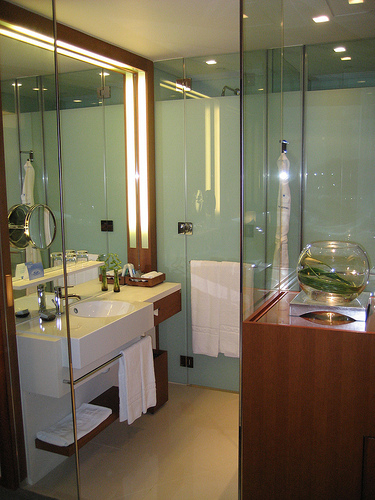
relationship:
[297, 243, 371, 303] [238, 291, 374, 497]
fishbowl on stand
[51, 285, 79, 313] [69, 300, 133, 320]
faucet over sink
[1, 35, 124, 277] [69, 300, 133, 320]
mirror over sink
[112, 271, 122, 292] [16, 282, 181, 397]
vase on counter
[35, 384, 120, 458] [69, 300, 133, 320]
shelf under sink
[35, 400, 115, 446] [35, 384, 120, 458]
towel on shelf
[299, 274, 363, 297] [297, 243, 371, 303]
foliage in fishbowl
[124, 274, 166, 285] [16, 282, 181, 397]
tray on counter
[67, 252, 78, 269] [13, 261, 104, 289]
glass on shelf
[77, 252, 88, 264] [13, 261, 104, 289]
glass on shelf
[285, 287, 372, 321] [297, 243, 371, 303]
base of fishbowl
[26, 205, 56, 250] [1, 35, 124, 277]
mirror on mirror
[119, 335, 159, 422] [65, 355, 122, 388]
towel on rack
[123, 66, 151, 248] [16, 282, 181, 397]
light over counter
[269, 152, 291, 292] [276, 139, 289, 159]
towel on hook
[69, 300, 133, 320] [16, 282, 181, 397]
sink on counter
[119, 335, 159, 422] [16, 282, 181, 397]
towel under counter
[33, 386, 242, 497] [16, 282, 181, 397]
floor under counter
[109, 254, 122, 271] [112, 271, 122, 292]
plant in vase